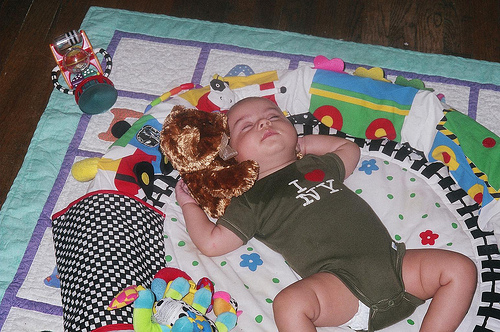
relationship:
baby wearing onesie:
[174, 96, 477, 332] [215, 152, 424, 332]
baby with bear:
[174, 96, 477, 332] [158, 104, 259, 220]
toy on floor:
[50, 27, 116, 112] [120, 16, 353, 56]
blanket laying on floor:
[4, 5, 496, 329] [1, 1, 498, 212]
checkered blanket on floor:
[46, 187, 169, 329] [15, 10, 465, 328]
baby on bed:
[174, 96, 477, 332] [3, 2, 498, 327]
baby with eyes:
[174, 96, 477, 332] [241, 111, 283, 129]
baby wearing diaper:
[174, 96, 477, 332] [336, 282, 384, 329]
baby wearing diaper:
[174, 96, 477, 332] [347, 297, 369, 330]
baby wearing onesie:
[174, 96, 477, 332] [219, 151, 430, 327]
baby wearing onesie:
[174, 96, 477, 332] [252, 170, 402, 304]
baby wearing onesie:
[176, 57, 429, 317] [219, 151, 430, 327]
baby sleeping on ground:
[174, 96, 477, 332] [5, 6, 484, 321]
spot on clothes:
[247, 167, 298, 193] [215, 153, 425, 332]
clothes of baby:
[215, 153, 425, 332] [174, 96, 477, 332]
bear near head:
[148, 67, 250, 208] [222, 98, 302, 172]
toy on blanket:
[50, 28, 118, 115] [4, 5, 496, 329]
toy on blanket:
[103, 266, 238, 327] [4, 5, 496, 329]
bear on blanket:
[158, 104, 259, 220] [4, 5, 496, 329]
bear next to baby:
[158, 104, 259, 220] [174, 96, 477, 332]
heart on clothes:
[304, 164, 329, 189] [207, 150, 434, 330]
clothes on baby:
[219, 151, 423, 330] [174, 96, 477, 332]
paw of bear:
[227, 155, 258, 195] [157, 100, 261, 219]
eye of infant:
[238, 119, 260, 138] [168, 95, 478, 330]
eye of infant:
[261, 103, 305, 138] [178, 72, 498, 327]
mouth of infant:
[260, 129, 282, 141] [168, 95, 478, 330]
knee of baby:
[436, 248, 483, 295] [174, 96, 477, 332]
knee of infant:
[261, 275, 301, 324] [161, 123, 493, 324]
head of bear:
[153, 95, 239, 173] [159, 102, 223, 175]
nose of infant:
[254, 112, 273, 132] [93, 57, 499, 330]